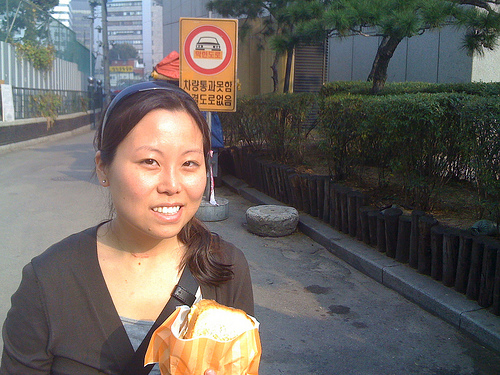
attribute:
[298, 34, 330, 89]
shutter — wooden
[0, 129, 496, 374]
drive — long, paved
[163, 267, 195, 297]
strap — black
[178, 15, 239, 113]
sign — orange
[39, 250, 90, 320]
shirt — dark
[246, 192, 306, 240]
stonebase — stone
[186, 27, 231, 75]
circle — red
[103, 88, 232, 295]
hair — brown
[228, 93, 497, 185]
hedge — green